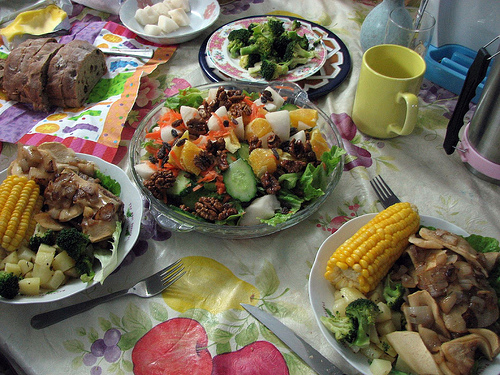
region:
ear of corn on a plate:
[326, 202, 421, 287]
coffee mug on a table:
[347, 40, 422, 140]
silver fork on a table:
[26, 255, 191, 332]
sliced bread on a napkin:
[0, 35, 120, 110]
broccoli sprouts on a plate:
[220, 15, 320, 75]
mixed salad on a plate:
[130, 80, 345, 230]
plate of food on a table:
[0, 135, 145, 305]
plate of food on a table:
[305, 210, 490, 370]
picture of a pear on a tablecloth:
[160, 247, 271, 332]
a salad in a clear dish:
[111, 77, 341, 241]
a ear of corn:
[316, 189, 426, 294]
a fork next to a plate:
[31, 264, 199, 344]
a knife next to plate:
[241, 299, 341, 371]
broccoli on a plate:
[223, 15, 315, 85]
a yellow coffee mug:
[338, 31, 440, 162]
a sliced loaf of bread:
[6, 29, 141, 121]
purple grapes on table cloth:
[61, 316, 146, 373]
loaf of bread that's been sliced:
[6, 38, 108, 111]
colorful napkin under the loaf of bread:
[1, 21, 178, 165]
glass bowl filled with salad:
[131, 84, 345, 236]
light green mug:
[355, 43, 425, 141]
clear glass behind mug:
[387, 5, 435, 59]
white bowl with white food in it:
[118, 1, 220, 44]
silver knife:
[241, 303, 353, 373]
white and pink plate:
[207, 14, 325, 81]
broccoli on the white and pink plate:
[227, 17, 316, 77]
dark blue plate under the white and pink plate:
[200, 15, 349, 99]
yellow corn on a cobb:
[324, 195, 417, 287]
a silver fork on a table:
[32, 260, 190, 330]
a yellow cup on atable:
[352, 46, 424, 139]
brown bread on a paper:
[3, 37, 107, 117]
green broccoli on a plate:
[208, 14, 324, 78]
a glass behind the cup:
[379, 9, 441, 39]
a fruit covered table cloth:
[84, 241, 321, 366]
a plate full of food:
[307, 209, 499, 365]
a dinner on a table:
[9, 0, 492, 369]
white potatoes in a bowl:
[113, 1, 226, 39]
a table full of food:
[0, 9, 490, 366]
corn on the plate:
[329, 180, 412, 288]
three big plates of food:
[2, 82, 481, 364]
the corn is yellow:
[340, 192, 427, 304]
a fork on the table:
[44, 264, 191, 328]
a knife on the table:
[230, 288, 344, 370]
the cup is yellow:
[350, 36, 428, 160]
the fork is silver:
[31, 261, 199, 328]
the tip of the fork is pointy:
[168, 251, 196, 283]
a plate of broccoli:
[212, 17, 328, 76]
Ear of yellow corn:
[321, 196, 422, 296]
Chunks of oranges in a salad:
[245, 145, 290, 180]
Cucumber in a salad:
[221, 157, 264, 204]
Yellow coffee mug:
[350, 37, 425, 143]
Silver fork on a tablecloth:
[23, 253, 216, 330]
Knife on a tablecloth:
[236, 292, 345, 372]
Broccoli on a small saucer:
[218, 5, 320, 79]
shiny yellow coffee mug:
[350, 42, 425, 142]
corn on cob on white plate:
[323, 200, 421, 295]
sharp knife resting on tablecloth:
[240, 302, 348, 374]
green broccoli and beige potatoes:
[321, 273, 441, 373]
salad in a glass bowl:
[128, 76, 343, 241]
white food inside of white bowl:
[116, 0, 220, 43]